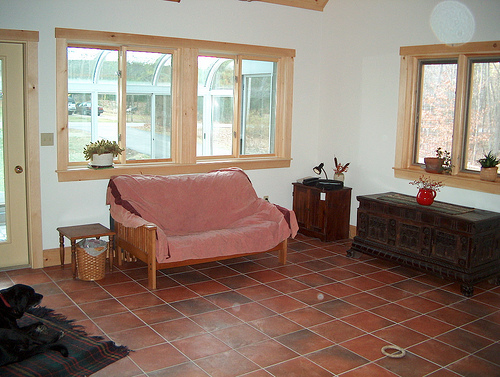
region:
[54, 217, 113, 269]
a small wooden table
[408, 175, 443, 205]
a red pot with red flowers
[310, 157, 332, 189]
a small black desk lamp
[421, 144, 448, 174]
a potted plant in a window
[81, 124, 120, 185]
a white flower pot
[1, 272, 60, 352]
a large black dog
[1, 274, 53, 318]
a black dog wearing a red collar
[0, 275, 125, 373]
a black dog laying on a blanket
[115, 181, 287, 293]
a wooden couch covered with a blanket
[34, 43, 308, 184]
a large window with wood trim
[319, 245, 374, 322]
part of a floor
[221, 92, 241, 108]
part of a window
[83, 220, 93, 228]
part of a stool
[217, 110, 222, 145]
part of a window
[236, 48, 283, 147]
edge of a window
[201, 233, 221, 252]
edge of a seat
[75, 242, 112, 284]
Light brown small wastebin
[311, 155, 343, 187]
Small black lamp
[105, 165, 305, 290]
Wooden loveseat with rose colored throw on it.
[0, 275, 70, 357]
Black dog with red collar.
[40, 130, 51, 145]
Double light switch on the wall.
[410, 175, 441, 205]
Red jug holding flowers.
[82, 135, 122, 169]
Plant in white pot on window sill.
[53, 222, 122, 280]
Small wood side table with bin under it.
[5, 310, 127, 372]
Black rug with red and yellow stripes.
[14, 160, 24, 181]
Copper colored door knob.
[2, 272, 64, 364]
A black dog laying down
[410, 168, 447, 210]
A red vase with flowers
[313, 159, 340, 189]
A black table lamp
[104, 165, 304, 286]
A couch with wooden arms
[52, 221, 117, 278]
A wooden end table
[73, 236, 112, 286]
A woven basket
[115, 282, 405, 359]
A rust colored tile floor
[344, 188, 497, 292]
An antique wooden chest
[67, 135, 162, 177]
A plant in a white pot on a window sill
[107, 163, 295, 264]
A pink blanket laying over the couch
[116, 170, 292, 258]
pink spread on brown wooden bench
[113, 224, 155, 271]
brown wooden bench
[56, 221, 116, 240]
brown top of side table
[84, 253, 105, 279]
brown trash can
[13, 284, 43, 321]
dog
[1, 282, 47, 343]
black dog lying on rug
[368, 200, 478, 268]
dark brown heavy cabinet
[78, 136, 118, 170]
green plant sitting in window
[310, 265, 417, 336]
brown black and red floor tiles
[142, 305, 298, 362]
brown black and red floor tiles